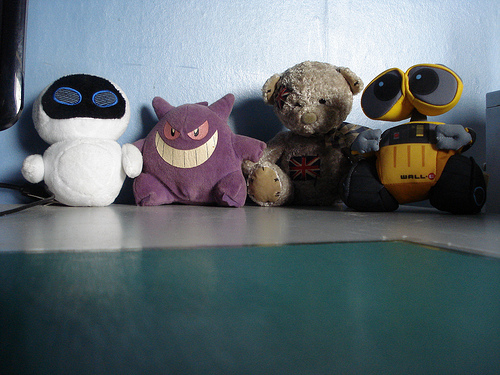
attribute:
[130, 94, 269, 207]
monster — purple, smiling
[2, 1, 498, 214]
wall — baby blue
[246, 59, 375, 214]
teddy bear — brown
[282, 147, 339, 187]
flag — Great Britain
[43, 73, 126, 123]
face — black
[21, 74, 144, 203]
toy — white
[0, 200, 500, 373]
table — green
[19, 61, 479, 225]
toys — stuffed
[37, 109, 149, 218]
animal — stuffed, white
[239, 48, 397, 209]
teddy bear — brown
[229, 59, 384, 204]
teddy bear — brown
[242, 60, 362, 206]
stuffed animal — beige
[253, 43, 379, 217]
teddy bear — brown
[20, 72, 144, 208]
animal — stuffed, black, white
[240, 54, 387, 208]
bear — brown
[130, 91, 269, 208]
toy — purple, white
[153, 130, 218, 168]
teeth — big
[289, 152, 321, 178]
flag — Great Britain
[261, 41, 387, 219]
bear — teddy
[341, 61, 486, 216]
stuffed animal — black, yellow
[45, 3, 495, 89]
wall — blue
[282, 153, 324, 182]
flag — British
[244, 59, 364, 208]
bear — teddy